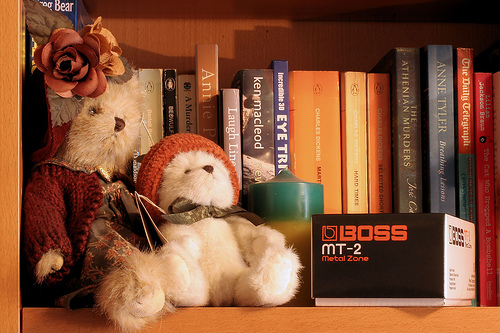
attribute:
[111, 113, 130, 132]
nose — Black 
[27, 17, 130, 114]
rose — pink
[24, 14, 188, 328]
teddy bear — white, beautiful